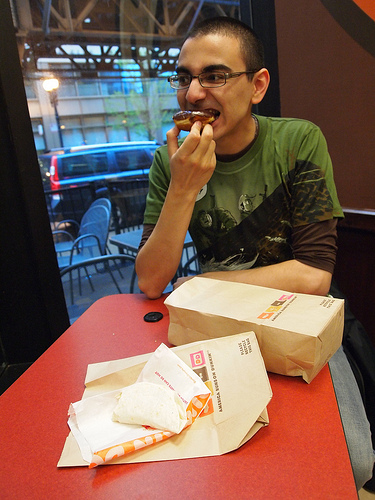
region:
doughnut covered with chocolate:
[172, 110, 214, 129]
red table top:
[258, 437, 338, 498]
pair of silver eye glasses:
[166, 70, 245, 90]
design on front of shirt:
[193, 197, 291, 268]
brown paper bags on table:
[69, 342, 267, 450]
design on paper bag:
[240, 286, 304, 337]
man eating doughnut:
[108, 12, 360, 280]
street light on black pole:
[37, 73, 72, 147]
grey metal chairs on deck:
[48, 198, 123, 288]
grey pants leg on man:
[330, 361, 373, 479]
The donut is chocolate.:
[167, 99, 216, 130]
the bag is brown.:
[164, 257, 350, 397]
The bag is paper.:
[160, 269, 348, 394]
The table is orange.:
[0, 283, 356, 491]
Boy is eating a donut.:
[160, 13, 277, 159]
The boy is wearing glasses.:
[165, 62, 264, 91]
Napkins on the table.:
[49, 324, 283, 472]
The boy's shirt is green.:
[132, 109, 345, 277]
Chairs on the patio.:
[48, 184, 195, 301]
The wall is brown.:
[270, 4, 373, 196]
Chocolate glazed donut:
[166, 107, 222, 132]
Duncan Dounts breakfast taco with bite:
[47, 362, 214, 453]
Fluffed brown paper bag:
[155, 261, 345, 380]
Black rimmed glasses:
[159, 64, 276, 94]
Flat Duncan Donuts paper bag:
[76, 333, 294, 465]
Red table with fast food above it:
[1, 253, 363, 499]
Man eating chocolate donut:
[135, 23, 343, 309]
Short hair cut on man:
[160, 12, 293, 140]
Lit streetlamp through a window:
[31, 62, 72, 97]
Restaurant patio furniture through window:
[42, 184, 120, 297]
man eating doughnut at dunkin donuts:
[65, 17, 337, 475]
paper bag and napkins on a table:
[51, 328, 288, 469]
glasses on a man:
[161, 63, 248, 90]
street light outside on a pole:
[32, 72, 80, 166]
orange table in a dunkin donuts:
[62, 287, 139, 352]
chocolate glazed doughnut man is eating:
[166, 103, 227, 133]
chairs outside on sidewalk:
[48, 194, 130, 275]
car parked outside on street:
[34, 139, 168, 240]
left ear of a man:
[243, 63, 277, 113]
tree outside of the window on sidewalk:
[100, 83, 159, 139]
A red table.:
[0, 287, 360, 493]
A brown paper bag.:
[161, 267, 348, 382]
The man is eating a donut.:
[136, 15, 317, 215]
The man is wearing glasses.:
[165, 16, 245, 136]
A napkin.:
[108, 375, 183, 435]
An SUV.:
[37, 135, 143, 229]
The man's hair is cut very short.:
[150, 11, 276, 161]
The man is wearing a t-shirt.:
[126, 116, 351, 301]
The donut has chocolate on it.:
[166, 99, 212, 133]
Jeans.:
[328, 336, 370, 483]